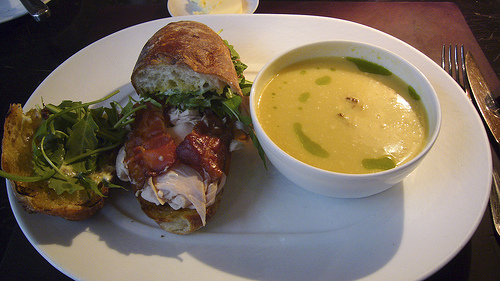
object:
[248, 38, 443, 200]
bowl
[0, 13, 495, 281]
plate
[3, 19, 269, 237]
sandwhich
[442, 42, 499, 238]
fork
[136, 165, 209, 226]
meat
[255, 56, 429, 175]
soup